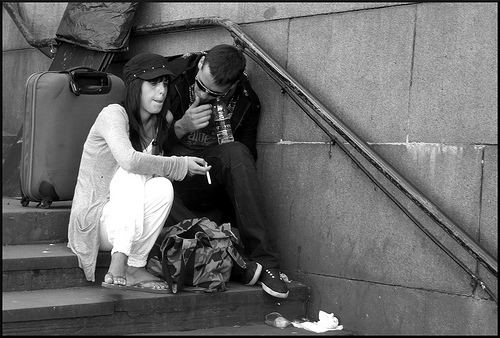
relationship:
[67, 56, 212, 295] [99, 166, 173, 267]
woman wearing pants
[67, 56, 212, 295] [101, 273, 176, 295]
woman wearing flip flops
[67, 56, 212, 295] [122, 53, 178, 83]
woman wearing a hat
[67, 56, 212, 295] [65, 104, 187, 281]
woman wearing a jacket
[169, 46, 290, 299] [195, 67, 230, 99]
man wearing sunglasses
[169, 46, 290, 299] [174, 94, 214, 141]
man has a hand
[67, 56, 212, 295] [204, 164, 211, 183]
woman holding cigarette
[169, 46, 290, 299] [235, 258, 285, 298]
man wearing shoes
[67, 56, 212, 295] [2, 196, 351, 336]
woman sitting on steps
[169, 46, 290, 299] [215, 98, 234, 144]
man has a bottle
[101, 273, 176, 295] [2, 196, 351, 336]
flip flops are on steps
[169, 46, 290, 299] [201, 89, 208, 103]
man touching nose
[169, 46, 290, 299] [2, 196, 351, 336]
man sitting on steps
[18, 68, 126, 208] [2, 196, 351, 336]
suitcase on steps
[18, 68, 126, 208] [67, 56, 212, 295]
suitcase behind woman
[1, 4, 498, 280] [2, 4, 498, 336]
handrail on wall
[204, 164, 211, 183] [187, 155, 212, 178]
cigarette in hand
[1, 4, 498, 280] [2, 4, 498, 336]
handrail attached to wall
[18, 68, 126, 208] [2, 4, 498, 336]
suitcase next to wall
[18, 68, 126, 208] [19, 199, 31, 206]
suitcase has a wheel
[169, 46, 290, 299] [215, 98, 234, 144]
man holding bottle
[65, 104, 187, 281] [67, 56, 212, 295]
jacket on woman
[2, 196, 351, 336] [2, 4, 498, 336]
steps are next to wall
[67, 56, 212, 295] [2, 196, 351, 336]
woman are sitting on steps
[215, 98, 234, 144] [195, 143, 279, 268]
bottle on leg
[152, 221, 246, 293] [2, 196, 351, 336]
bag on steps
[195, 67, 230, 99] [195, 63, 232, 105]
sunglasses are on face